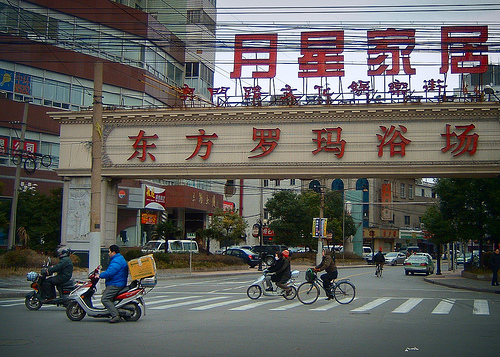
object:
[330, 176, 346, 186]
arch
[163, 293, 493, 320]
road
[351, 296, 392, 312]
stripes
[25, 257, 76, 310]
scooters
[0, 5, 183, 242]
building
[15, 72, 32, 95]
windows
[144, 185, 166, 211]
signs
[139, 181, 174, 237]
store front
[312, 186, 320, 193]
lights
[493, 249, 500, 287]
person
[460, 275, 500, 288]
sidewalk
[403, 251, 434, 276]
vehicles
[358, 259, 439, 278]
road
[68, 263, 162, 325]
motorcycle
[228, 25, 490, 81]
oriental writing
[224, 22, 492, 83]
structure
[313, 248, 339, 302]
people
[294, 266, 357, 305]
bicycles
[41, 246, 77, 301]
people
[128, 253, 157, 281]
cardboard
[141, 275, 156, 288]
items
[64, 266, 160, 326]
silver and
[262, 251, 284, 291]
person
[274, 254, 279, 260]
mask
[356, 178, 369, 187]
arches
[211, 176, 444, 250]
building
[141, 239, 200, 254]
vehicles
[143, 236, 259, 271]
background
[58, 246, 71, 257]
cap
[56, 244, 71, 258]
head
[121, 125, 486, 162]
writing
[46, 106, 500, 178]
structure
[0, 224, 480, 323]
street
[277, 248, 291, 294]
person wearing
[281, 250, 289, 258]
cap